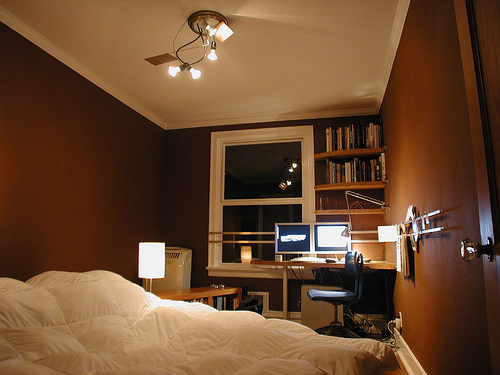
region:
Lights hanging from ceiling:
[165, 0, 234, 81]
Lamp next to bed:
[136, 240, 169, 295]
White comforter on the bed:
[0, 271, 392, 373]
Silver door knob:
[457, 236, 496, 264]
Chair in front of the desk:
[308, 250, 362, 331]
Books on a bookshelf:
[312, 118, 385, 192]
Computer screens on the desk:
[274, 220, 354, 265]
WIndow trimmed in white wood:
[206, 122, 316, 260]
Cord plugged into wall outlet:
[386, 310, 404, 339]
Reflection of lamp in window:
[237, 239, 255, 264]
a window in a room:
[213, 137, 310, 262]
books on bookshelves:
[315, 123, 387, 188]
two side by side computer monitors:
[267, 218, 354, 256]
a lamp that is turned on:
[137, 238, 169, 279]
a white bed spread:
[2, 263, 386, 373]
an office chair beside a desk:
[304, 255, 374, 335]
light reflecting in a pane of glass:
[274, 150, 301, 194]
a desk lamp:
[336, 185, 367, 240]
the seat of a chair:
[308, 283, 354, 304]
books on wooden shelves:
[180, 288, 238, 315]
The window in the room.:
[212, 125, 309, 264]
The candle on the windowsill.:
[240, 243, 251, 265]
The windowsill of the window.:
[204, 256, 314, 276]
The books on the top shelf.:
[319, 123, 384, 144]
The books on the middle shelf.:
[324, 154, 390, 181]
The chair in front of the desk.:
[305, 246, 352, 338]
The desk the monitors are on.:
[250, 255, 400, 275]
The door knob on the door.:
[456, 234, 494, 265]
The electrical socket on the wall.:
[394, 310, 405, 326]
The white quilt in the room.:
[5, 257, 406, 374]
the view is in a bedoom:
[166, 170, 441, 342]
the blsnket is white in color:
[79, 259, 231, 373]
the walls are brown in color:
[26, 140, 89, 230]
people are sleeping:
[28, 243, 173, 365]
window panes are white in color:
[211, 114, 321, 209]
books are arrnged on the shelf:
[323, 121, 394, 175]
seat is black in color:
[316, 263, 355, 306]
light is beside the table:
[124, 240, 175, 289]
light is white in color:
[125, 239, 180, 294]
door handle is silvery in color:
[456, 230, 481, 268]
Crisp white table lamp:
[133, 237, 173, 286]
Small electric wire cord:
[388, 307, 408, 332]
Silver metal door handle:
[454, 235, 493, 265]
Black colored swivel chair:
[310, 248, 367, 306]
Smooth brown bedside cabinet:
[201, 285, 212, 297]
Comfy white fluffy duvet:
[158, 320, 280, 370]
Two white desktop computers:
[272, 220, 354, 255]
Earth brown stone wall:
[423, 278, 462, 348]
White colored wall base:
[398, 338, 416, 373]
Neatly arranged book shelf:
[324, 113, 390, 184]